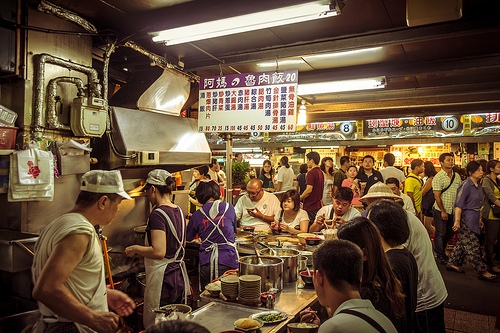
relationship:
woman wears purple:
[185, 176, 242, 283] [184, 199, 240, 269]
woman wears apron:
[121, 166, 195, 322] [138, 204, 190, 317]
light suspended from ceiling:
[146, 1, 347, 48] [77, 3, 496, 55]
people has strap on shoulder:
[311, 240, 398, 332] [339, 303, 386, 332]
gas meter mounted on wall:
[64, 88, 116, 143] [26, 26, 115, 162]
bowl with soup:
[299, 267, 314, 285] [300, 267, 315, 276]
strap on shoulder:
[438, 169, 460, 197] [446, 169, 463, 187]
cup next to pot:
[260, 290, 277, 304] [235, 254, 286, 305]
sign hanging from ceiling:
[195, 68, 302, 138] [77, 3, 496, 55]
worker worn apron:
[121, 166, 195, 322] [138, 204, 190, 317]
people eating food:
[225, 171, 411, 308] [240, 221, 315, 256]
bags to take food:
[5, 144, 60, 207] [233, 245, 302, 299]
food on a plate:
[259, 309, 281, 322] [250, 308, 290, 326]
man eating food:
[239, 176, 280, 228] [240, 221, 315, 256]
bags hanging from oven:
[5, 144, 60, 207] [6, 38, 85, 216]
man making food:
[27, 163, 145, 330] [137, 285, 188, 333]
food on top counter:
[208, 233, 300, 318] [197, 227, 314, 331]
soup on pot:
[298, 267, 314, 286] [235, 254, 286, 305]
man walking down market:
[298, 149, 330, 229] [228, 140, 371, 208]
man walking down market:
[430, 149, 463, 254] [349, 134, 499, 227]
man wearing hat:
[359, 182, 416, 230] [352, 177, 403, 201]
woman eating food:
[269, 187, 310, 237] [270, 219, 283, 232]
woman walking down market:
[339, 164, 360, 198] [228, 140, 371, 208]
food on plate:
[259, 309, 281, 322] [250, 308, 290, 326]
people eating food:
[215, 140, 485, 242] [240, 201, 339, 249]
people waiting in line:
[215, 140, 485, 242] [266, 144, 445, 190]